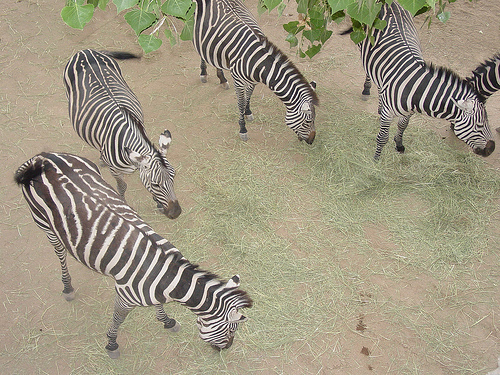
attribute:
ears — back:
[116, 129, 178, 168]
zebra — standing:
[186, 0, 335, 176]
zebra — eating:
[15, 152, 253, 356]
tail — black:
[10, 145, 42, 188]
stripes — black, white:
[61, 63, 123, 133]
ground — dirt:
[258, 168, 488, 373]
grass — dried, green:
[332, 164, 470, 247]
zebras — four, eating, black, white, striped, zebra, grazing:
[5, 6, 490, 355]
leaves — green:
[72, 4, 196, 38]